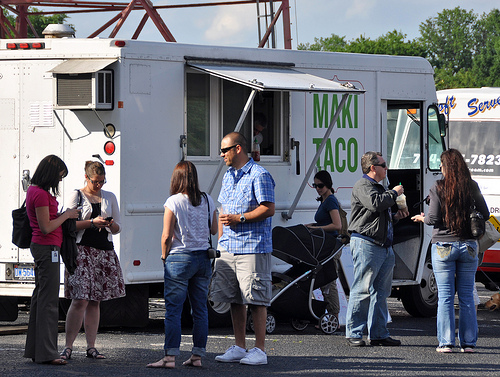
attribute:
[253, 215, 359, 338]
stroller — black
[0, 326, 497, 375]
ground — cement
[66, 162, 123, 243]
cardigan — white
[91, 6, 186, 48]
pole — green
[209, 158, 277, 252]
shirt — blue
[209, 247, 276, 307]
shorts — khaki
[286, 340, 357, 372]
ground — cement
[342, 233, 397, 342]
jacket — green